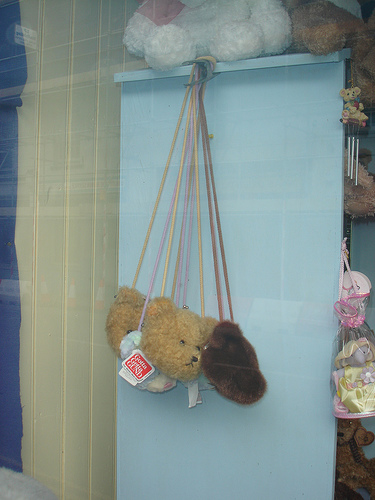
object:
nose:
[193, 357, 198, 362]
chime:
[347, 135, 351, 177]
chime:
[350, 136, 355, 180]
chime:
[355, 138, 360, 186]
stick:
[339, 115, 365, 127]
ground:
[330, 109, 333, 129]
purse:
[104, 289, 217, 392]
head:
[200, 319, 267, 405]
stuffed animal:
[108, 285, 266, 410]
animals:
[122, 0, 375, 65]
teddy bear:
[103, 285, 220, 383]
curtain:
[0, 0, 27, 475]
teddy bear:
[122, 0, 291, 74]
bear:
[339, 86, 368, 128]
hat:
[334, 329, 375, 370]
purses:
[104, 68, 266, 404]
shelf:
[111, 44, 346, 83]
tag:
[119, 348, 155, 386]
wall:
[0, 0, 120, 500]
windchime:
[338, 52, 374, 187]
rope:
[131, 56, 233, 323]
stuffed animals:
[108, 284, 266, 403]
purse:
[119, 331, 160, 392]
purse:
[200, 320, 266, 405]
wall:
[350, 215, 374, 281]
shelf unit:
[102, 0, 375, 499]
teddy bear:
[286, 1, 375, 57]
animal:
[333, 337, 375, 413]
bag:
[324, 273, 374, 420]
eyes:
[180, 340, 200, 351]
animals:
[342, 60, 375, 220]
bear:
[201, 320, 267, 402]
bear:
[142, 296, 220, 382]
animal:
[105, 285, 220, 392]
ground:
[2, 458, 120, 500]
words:
[127, 354, 147, 377]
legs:
[106, 304, 142, 357]